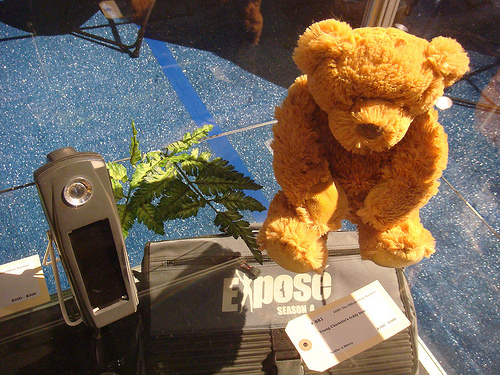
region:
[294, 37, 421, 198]
brown teddy bear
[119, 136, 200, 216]
green leaves on the table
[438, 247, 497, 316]
glass table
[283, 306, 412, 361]
a tag on the table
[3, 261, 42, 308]
a tag on the table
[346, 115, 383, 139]
nose on teddy bear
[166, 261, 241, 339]
a shadow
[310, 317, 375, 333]
print on the tag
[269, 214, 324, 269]
light on the teddy bear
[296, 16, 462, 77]
ears of the teddy bear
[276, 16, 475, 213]
brown bear above ground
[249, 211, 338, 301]
leg of the bear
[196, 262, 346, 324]
white word under the bear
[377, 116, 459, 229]
left arm of bear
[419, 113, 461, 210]
light hitting the arm of the bear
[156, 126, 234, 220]
leaves on the ground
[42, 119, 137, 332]
item next to bear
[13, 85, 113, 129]
blue floor in the room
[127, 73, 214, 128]
blue line on tile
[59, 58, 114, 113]
white dots on the floor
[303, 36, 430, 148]
face of the doll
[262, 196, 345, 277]
leg of the doll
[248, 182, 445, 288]
two legs of doll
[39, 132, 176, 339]
a small object on ground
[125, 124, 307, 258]
a piece of green leaf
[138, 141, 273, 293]
a nice view of green leaf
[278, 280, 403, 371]
a small post card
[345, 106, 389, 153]
nose of the doll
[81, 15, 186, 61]
small iron stand on ground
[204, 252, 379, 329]
name of the box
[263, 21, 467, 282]
the brown stuffed bear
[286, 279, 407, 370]
the tag in front of the bear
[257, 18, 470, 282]
the brown stuffed teddy bear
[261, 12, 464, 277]
the teddy bear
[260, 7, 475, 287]
the teddy bear plushie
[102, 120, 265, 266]
the leaves next to the bear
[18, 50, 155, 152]
the blue flooring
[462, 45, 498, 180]
the reflection on the window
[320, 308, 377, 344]
the words on the tag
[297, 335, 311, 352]
the hole on the tag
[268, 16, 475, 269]
gold teddy bear with tag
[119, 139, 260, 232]
green artificial fern leaves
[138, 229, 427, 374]
brown expose' case under glass shelf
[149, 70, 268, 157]
blue tape on the floor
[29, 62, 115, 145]
blue floor tile with glitter in it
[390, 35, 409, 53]
heart button on bear's head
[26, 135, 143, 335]
brown electronic item with gold button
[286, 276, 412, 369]
identification tag for teddy bear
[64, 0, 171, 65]
black metal leg for stool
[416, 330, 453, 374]
white metal window case